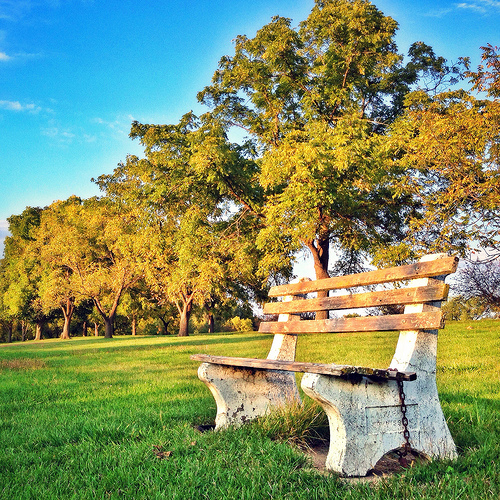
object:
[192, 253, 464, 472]
bench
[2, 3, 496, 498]
park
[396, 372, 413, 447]
chain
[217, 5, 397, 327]
tree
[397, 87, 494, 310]
tree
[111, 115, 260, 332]
tree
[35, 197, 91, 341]
tree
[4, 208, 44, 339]
tree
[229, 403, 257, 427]
peeling paint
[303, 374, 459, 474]
legs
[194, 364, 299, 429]
legs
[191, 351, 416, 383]
seat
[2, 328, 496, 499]
grass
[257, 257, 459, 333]
back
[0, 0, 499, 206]
sky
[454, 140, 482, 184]
leaves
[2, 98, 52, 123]
clouds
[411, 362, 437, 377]
crack